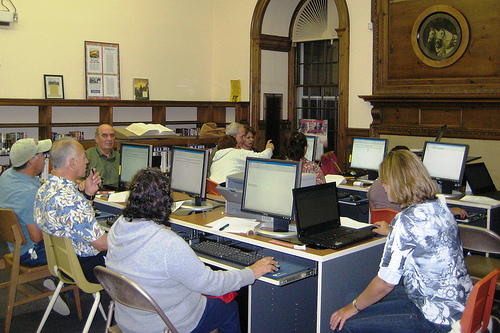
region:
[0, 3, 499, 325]
Group of people sitting in room with computers.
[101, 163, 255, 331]
Lady sitting in chair wearing grey sweater.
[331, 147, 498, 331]
Lady sitting in orange chair wearing blue design shirt.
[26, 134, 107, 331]
Man sitting in green chair wearing floral shirt.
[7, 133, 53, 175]
Light green baseball cap with rim.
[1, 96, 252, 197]
Brown book shelf containing books.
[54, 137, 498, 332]
Multiple computers on desks.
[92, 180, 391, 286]
Papers pm brown, blue, and white desk.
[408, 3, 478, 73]
Decorative horse design on wall.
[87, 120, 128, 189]
Man wearing dark green shirt.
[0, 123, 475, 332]
people sitting down in front of computers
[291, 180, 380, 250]
a black laptop on a desk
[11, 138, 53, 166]
a man wearing a light green cap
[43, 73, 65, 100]
a framed picture on top of a bookshelf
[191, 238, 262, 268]
a black computer keyboard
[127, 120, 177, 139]
an opened book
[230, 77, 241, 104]
a yellow sheet of paper on a wall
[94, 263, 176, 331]
a gray metallic chair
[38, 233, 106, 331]
a light green plastic chair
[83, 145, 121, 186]
man wearing a green shirt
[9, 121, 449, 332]
people all sitting at computers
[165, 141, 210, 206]
everyone has a flatscreen monitor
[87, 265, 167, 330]
a taupe colored metal folding chair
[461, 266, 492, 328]
the back of a molded orange stacking chair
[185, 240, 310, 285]
a sliding shelf pulls out from table to hold keyboard and mouse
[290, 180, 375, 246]
lady seated at the end uses a laptop.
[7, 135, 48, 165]
man wears a pastel green baseball cap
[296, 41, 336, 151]
the dark window shows it is evening time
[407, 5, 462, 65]
a round picture framed oner the mantle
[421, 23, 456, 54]
a black and white picture of two horses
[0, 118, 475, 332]
A group of people sitting around computers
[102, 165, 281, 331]
Woman in hoodie sitting in front of a computer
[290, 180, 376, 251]
Black laptop on the desk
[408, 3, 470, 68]
A picture of two horses in a circular frame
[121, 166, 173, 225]
A woman's black hair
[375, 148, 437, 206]
A woman's head with blonde hair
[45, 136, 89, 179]
A man's head with grey hair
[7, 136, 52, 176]
A man's head with a baseball cap on it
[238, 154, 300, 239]
Dell computer monitor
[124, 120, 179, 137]
Open book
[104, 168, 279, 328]
Woman sitting in a metal folding chair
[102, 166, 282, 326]
Woman sitting in front of a computer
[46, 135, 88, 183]
Man with gray hair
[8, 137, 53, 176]
Man wearing a baseball cap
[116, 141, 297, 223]
Three computer monitors on a desk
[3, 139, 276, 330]
Three people sitting in front of computer monitors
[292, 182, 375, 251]
Black laptop computer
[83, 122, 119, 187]
Bald man wearing a green shirt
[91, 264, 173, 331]
Metal folding chair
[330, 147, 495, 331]
Woman sitting in a chair